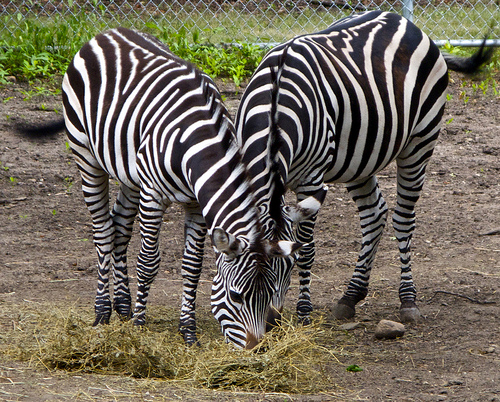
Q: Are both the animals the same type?
A: Yes, all the animals are zebras.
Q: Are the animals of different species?
A: No, all the animals are zebras.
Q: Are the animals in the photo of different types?
A: No, all the animals are zebras.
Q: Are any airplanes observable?
A: No, there are no airplanes.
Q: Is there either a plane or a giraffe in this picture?
A: No, there are no airplanes or giraffes.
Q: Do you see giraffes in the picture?
A: No, there are no giraffes.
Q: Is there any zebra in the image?
A: Yes, there is a zebra.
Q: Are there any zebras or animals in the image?
A: Yes, there is a zebra.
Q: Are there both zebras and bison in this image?
A: No, there is a zebra but no bison.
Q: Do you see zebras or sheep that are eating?
A: Yes, the zebra is eating.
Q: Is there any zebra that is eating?
A: Yes, there is a zebra that is eating.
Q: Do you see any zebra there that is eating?
A: Yes, there is a zebra that is eating.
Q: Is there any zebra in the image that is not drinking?
A: Yes, there is a zebra that is eating.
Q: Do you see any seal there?
A: No, there are no seals.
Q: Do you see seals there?
A: No, there are no seals.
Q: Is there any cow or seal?
A: No, there are no seals or cows.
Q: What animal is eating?
A: The animal is a zebra.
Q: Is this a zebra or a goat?
A: This is a zebra.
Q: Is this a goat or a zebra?
A: This is a zebra.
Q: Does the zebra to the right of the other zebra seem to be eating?
A: Yes, the zebra is eating.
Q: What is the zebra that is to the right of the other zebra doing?
A: The zebra is eating.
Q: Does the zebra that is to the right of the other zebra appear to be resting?
A: No, the zebra is eating.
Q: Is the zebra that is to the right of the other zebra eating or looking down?
A: The zebra is eating.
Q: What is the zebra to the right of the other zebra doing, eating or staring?
A: The zebra is eating.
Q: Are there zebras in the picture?
A: Yes, there is a zebra.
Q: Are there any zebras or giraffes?
A: Yes, there is a zebra.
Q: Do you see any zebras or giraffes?
A: Yes, there is a zebra.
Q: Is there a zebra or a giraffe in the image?
A: Yes, there is a zebra.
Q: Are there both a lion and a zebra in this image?
A: No, there is a zebra but no lions.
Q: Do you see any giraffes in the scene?
A: No, there are no giraffes.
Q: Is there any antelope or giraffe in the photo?
A: No, there are no giraffes or antelopes.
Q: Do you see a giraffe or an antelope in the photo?
A: No, there are no giraffes or antelopes.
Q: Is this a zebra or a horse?
A: This is a zebra.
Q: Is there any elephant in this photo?
A: No, there are no elephants.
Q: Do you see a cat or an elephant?
A: No, there are no elephants or cats.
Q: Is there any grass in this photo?
A: Yes, there is grass.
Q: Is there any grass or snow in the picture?
A: Yes, there is grass.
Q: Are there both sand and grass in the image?
A: No, there is grass but no sand.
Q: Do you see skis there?
A: No, there are no skis.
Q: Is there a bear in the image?
A: No, there are no bears.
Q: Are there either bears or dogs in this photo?
A: No, there are no bears or dogs.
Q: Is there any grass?
A: Yes, there is grass.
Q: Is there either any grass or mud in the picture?
A: Yes, there is grass.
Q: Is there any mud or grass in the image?
A: Yes, there is grass.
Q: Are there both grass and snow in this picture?
A: No, there is grass but no snow.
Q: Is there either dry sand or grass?
A: Yes, there is dry grass.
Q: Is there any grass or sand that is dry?
A: Yes, the grass is dry.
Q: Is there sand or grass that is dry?
A: Yes, the grass is dry.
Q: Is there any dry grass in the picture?
A: Yes, there is dry grass.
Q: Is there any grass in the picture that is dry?
A: Yes, there is grass that is dry.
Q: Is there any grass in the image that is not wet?
A: Yes, there is dry grass.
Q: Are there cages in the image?
A: No, there are no cages.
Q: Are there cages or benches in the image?
A: No, there are no cages or benches.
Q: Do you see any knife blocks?
A: No, there are no knife blocks.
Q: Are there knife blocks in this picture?
A: No, there are no knife blocks.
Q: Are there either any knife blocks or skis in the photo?
A: No, there are no knife blocks or skis.